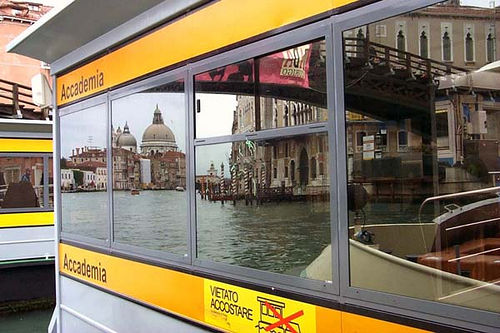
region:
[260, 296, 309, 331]
red X on the sign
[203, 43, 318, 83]
banner hanging off the bridge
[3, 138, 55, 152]
thick black strip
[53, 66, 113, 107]
black writing on a yellow background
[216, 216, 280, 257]
ripples in the water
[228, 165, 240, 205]
pole sticking out of the water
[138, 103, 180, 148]
round dome on the top of the building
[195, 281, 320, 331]
black, yellow, and red sign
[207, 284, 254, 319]
black writing in all caps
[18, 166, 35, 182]
person standing up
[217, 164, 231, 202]
pole sticking out of the water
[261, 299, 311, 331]
red X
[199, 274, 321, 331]
yellow, black, and red sign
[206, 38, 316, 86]
banner hanging over the side of the bridge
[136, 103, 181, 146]
large round dome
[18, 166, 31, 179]
top half of a person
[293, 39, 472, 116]
bridge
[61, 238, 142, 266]
thin black line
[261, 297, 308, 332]
Red X under the window.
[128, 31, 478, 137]
The reflection of a bridge in the window.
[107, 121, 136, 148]
Three rounded roof tops reflecting in the windows.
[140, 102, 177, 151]
A large rounded pointy rooftop reflecting in the window.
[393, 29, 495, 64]
Five windows in a row above a bridge to the right.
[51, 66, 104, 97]
The word Accademia on the top side of a building.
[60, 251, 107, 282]
The word Accademia on the bottom side of a building.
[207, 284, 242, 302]
The word Vetato to the left of a giant X.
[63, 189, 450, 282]
Water going under a bridge flowing through a city.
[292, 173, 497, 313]
A large boat outside the building.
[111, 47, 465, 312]
this is a ship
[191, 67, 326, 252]
this is a window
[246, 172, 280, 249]
the glass is transparent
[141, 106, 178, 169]
this is a temple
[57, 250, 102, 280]
this is a writing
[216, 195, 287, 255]
this is a water body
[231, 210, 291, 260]
the water is calm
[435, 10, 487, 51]
this is a building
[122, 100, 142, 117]
this is the sky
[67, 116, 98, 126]
the sky is blue in color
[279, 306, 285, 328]
the cross is red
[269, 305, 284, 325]
the cross is red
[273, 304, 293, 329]
the cross is red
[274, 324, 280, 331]
the cross is red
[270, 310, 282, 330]
the cross is red